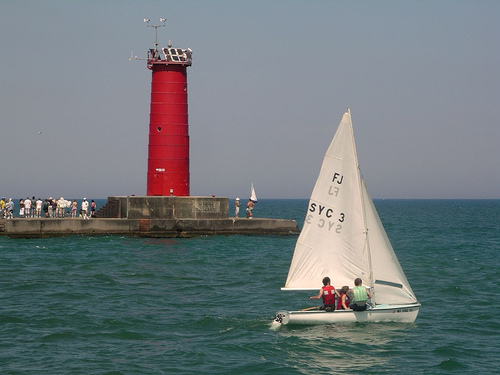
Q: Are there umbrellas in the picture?
A: No, there are no umbrellas.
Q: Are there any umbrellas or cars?
A: No, there are no umbrellas or cars.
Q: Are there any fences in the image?
A: No, there are no fences.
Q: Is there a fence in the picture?
A: No, there are no fences.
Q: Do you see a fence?
A: No, there are no fences.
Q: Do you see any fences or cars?
A: No, there are no fences or cars.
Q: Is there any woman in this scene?
A: Yes, there is a woman.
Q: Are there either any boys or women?
A: Yes, there is a woman.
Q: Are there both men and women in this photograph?
A: Yes, there are both a woman and a man.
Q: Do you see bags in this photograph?
A: No, there are no bags.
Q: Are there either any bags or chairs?
A: No, there are no bags or chairs.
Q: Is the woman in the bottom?
A: Yes, the woman is in the bottom of the image.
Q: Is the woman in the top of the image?
A: No, the woman is in the bottom of the image.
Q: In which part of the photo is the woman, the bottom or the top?
A: The woman is in the bottom of the image.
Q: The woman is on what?
A: The woman is on the sailboat.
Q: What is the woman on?
A: The woman is on the sailboat.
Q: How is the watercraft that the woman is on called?
A: The watercraft is a sailboat.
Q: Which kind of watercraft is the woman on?
A: The woman is on the sailboat.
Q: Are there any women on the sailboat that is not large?
A: Yes, there is a woman on the sailboat.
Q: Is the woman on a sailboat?
A: Yes, the woman is on a sailboat.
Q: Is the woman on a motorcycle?
A: No, the woman is on a sailboat.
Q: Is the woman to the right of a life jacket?
A: Yes, the woman is to the right of a life jacket.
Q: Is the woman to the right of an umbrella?
A: No, the woman is to the right of a life jacket.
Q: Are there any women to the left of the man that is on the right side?
A: Yes, there is a woman to the left of the man.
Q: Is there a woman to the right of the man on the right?
A: No, the woman is to the left of the man.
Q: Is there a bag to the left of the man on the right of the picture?
A: No, there is a woman to the left of the man.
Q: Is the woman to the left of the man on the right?
A: Yes, the woman is to the left of the man.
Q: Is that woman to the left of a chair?
A: No, the woman is to the left of the man.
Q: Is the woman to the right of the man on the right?
A: No, the woman is to the left of the man.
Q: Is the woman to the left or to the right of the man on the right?
A: The woman is to the left of the man.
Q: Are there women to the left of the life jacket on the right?
A: Yes, there is a woman to the left of the life vest.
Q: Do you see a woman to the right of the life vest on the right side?
A: No, the woman is to the left of the life vest.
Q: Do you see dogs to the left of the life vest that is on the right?
A: No, there is a woman to the left of the life vest.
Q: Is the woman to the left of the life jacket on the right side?
A: Yes, the woman is to the left of the life jacket.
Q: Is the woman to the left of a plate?
A: No, the woman is to the left of the life jacket.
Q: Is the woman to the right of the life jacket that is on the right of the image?
A: No, the woman is to the left of the life jacket.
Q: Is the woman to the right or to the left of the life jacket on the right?
A: The woman is to the left of the life vest.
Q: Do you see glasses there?
A: No, there are no glasses.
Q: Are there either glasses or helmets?
A: No, there are no glasses or helmets.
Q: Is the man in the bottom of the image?
A: Yes, the man is in the bottom of the image.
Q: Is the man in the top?
A: No, the man is in the bottom of the image.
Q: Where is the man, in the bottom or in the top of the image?
A: The man is in the bottom of the image.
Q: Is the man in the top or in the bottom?
A: The man is in the bottom of the image.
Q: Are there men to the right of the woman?
A: Yes, there is a man to the right of the woman.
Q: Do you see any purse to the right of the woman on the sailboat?
A: No, there is a man to the right of the woman.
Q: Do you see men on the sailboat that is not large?
A: Yes, there is a man on the sailboat.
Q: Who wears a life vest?
A: The man wears a life vest.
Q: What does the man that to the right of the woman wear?
A: The man wears a life vest.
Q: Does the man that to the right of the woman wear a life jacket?
A: Yes, the man wears a life jacket.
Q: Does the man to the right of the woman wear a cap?
A: No, the man wears a life jacket.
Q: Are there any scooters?
A: No, there are no scooters.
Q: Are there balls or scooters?
A: No, there are no scooters or balls.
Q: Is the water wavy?
A: Yes, the water is wavy.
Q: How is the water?
A: The water is wavy.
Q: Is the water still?
A: No, the water is wavy.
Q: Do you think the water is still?
A: No, the water is wavy.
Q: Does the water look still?
A: No, the water is wavy.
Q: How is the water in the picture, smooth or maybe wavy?
A: The water is wavy.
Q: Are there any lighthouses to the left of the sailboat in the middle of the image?
A: Yes, there is a lighthouse to the left of the sailboat.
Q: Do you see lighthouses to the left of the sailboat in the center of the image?
A: Yes, there is a lighthouse to the left of the sailboat.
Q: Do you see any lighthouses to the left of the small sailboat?
A: Yes, there is a lighthouse to the left of the sailboat.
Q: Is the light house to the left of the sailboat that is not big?
A: Yes, the light house is to the left of the sailboat.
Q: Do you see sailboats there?
A: Yes, there is a sailboat.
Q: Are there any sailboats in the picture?
A: Yes, there is a sailboat.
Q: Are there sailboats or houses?
A: Yes, there is a sailboat.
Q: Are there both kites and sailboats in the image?
A: No, there is a sailboat but no kites.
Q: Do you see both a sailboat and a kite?
A: No, there is a sailboat but no kites.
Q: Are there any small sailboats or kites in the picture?
A: Yes, there is a small sailboat.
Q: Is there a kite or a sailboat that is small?
A: Yes, the sailboat is small.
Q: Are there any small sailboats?
A: Yes, there is a small sailboat.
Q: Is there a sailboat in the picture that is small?
A: Yes, there is a sailboat that is small.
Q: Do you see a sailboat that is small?
A: Yes, there is a sailboat that is small.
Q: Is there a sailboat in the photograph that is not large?
A: Yes, there is a small sailboat.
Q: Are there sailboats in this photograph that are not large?
A: Yes, there is a small sailboat.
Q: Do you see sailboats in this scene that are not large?
A: Yes, there is a small sailboat.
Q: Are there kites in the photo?
A: No, there are no kites.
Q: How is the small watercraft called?
A: The watercraft is a sailboat.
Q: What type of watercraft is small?
A: The watercraft is a sailboat.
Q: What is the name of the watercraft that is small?
A: The watercraft is a sailboat.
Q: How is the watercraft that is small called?
A: The watercraft is a sailboat.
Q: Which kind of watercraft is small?
A: The watercraft is a sailboat.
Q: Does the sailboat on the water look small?
A: Yes, the sailboat is small.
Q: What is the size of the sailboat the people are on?
A: The sailboat is small.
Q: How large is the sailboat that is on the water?
A: The sailboat is small.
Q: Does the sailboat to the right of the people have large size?
A: No, the sailboat is small.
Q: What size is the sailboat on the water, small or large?
A: The sailboat is small.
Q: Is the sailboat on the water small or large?
A: The sailboat is small.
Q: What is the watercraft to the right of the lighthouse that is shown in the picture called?
A: The watercraft is a sailboat.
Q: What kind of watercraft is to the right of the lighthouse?
A: The watercraft is a sailboat.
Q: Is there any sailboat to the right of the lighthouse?
A: Yes, there is a sailboat to the right of the lighthouse.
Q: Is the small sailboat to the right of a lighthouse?
A: Yes, the sailboat is to the right of a lighthouse.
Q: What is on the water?
A: The sailboat is on the water.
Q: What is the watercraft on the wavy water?
A: The watercraft is a sailboat.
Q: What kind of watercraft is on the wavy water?
A: The watercraft is a sailboat.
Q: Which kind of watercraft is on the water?
A: The watercraft is a sailboat.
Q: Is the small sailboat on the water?
A: Yes, the sailboat is on the water.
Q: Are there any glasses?
A: No, there are no glasses.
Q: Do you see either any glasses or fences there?
A: No, there are no glasses or fences.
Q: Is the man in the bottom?
A: Yes, the man is in the bottom of the image.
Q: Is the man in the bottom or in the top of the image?
A: The man is in the bottom of the image.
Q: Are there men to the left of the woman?
A: Yes, there is a man to the left of the woman.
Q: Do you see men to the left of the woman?
A: Yes, there is a man to the left of the woman.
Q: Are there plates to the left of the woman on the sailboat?
A: No, there is a man to the left of the woman.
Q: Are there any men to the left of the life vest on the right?
A: Yes, there is a man to the left of the life vest.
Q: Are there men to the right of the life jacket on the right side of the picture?
A: No, the man is to the left of the life vest.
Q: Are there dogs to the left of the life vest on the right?
A: No, there is a man to the left of the life jacket.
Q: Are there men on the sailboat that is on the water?
A: Yes, there is a man on the sailboat.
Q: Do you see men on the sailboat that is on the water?
A: Yes, there is a man on the sailboat.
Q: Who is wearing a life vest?
A: The man is wearing a life vest.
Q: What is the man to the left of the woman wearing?
A: The man is wearing a life vest.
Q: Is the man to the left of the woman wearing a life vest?
A: Yes, the man is wearing a life vest.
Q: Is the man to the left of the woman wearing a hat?
A: No, the man is wearing a life vest.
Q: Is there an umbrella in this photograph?
A: No, there are no umbrellas.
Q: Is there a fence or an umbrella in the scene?
A: No, there are no umbrellas or fences.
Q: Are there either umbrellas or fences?
A: No, there are no umbrellas or fences.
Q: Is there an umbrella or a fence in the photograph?
A: No, there are no umbrellas or fences.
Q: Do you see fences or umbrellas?
A: No, there are no umbrellas or fences.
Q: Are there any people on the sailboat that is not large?
A: Yes, there are people on the sailboat.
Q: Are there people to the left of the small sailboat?
A: Yes, there are people to the left of the sailboat.